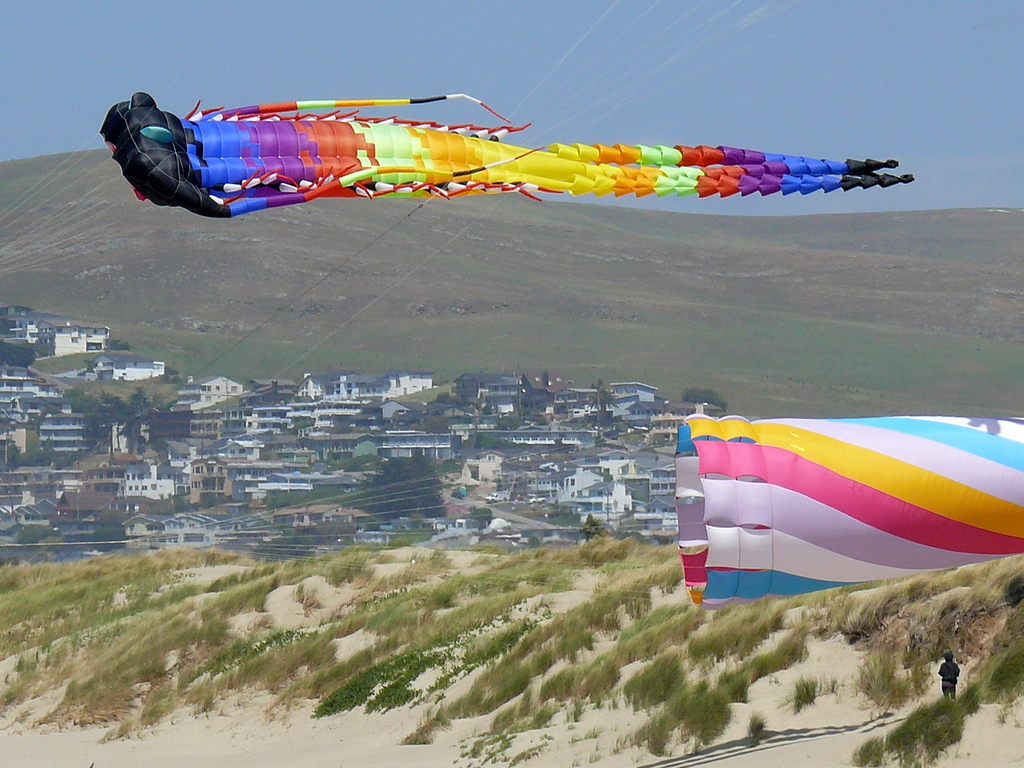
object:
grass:
[0, 535, 1024, 768]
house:
[113, 450, 174, 500]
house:
[191, 455, 234, 503]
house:
[273, 505, 369, 529]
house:
[373, 430, 453, 460]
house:
[477, 423, 597, 445]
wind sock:
[99, 92, 915, 218]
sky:
[0, 0, 1020, 218]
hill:
[0, 536, 1019, 765]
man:
[937, 651, 959, 701]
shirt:
[937, 660, 959, 684]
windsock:
[673, 414, 1024, 610]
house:
[91, 350, 163, 381]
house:
[329, 367, 435, 398]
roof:
[295, 369, 435, 388]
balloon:
[673, 414, 1024, 612]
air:
[0, 0, 1022, 764]